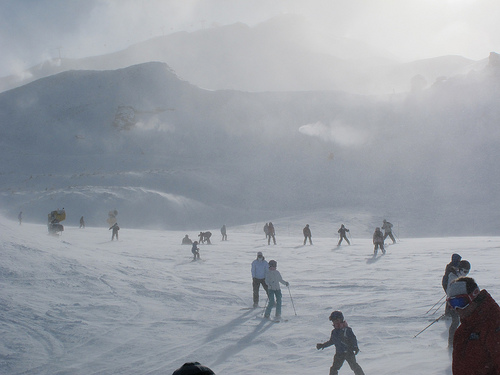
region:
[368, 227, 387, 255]
person sking on snow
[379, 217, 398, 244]
person sking on snow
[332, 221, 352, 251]
person sking on snow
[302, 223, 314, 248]
person sking on snow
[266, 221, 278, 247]
person sking on snow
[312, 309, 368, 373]
person sking on snow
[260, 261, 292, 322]
person sking on snow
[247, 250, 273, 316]
person sking on snow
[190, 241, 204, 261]
person sking on snow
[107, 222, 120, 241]
person sking on snow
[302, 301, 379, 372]
this is a person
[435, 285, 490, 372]
this is a person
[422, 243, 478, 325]
this is a person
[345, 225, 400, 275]
this is a person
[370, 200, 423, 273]
this is a person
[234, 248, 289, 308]
this is a person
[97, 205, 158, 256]
this is a person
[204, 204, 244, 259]
this is a person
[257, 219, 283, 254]
this is a person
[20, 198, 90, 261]
this is a person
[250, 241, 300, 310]
skier on hill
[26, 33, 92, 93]
white snow on hill side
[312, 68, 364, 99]
white snow on hill side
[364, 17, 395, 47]
white snow on hill side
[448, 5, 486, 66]
white snow on hill side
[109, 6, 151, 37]
white snow on hill side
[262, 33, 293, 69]
white snow on hill side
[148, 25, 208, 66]
white snow on hill side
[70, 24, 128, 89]
white snow on hill side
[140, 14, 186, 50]
white snow on hill side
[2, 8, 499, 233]
high snow covered mountains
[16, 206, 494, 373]
a large group of skiers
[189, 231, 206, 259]
two small children skiing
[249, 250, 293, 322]
two people in light colored coats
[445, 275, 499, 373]
a man with skiing glasses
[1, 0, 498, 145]
snow flying above mountains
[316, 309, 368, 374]
a child who skies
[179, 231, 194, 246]
a person sitting on the ground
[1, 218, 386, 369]
a snow covered ski path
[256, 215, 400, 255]
a group of people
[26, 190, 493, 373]
large group of people skiing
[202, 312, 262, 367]
shadow of two skiers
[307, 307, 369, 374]
child in the foreground skiing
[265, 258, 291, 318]
woman wearing white coat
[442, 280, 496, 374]
man wearing black coat and ski goggles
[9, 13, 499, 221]
hazy sky around mountains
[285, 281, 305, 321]
ski pole of woman wearing white coat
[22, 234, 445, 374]
tracks in the snow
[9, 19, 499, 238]
mountains behind snowy area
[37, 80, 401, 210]
patches of snow on the mountains